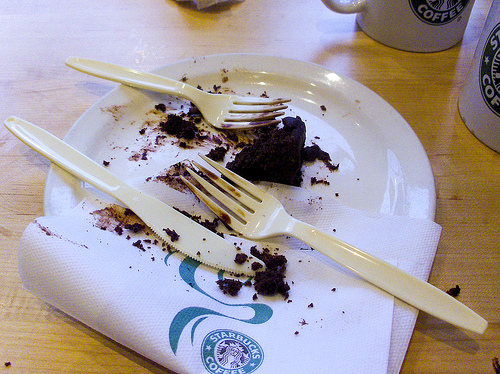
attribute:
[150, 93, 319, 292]
food — chocolate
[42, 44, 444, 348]
plate — white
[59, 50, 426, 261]
forks — plastic, tined, handled, used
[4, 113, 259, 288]
knife — handled, plastic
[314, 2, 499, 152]
mug — white, glass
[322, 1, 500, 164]
mugs — grouped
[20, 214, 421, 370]
napkin — white, paper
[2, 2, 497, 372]
table — wooden